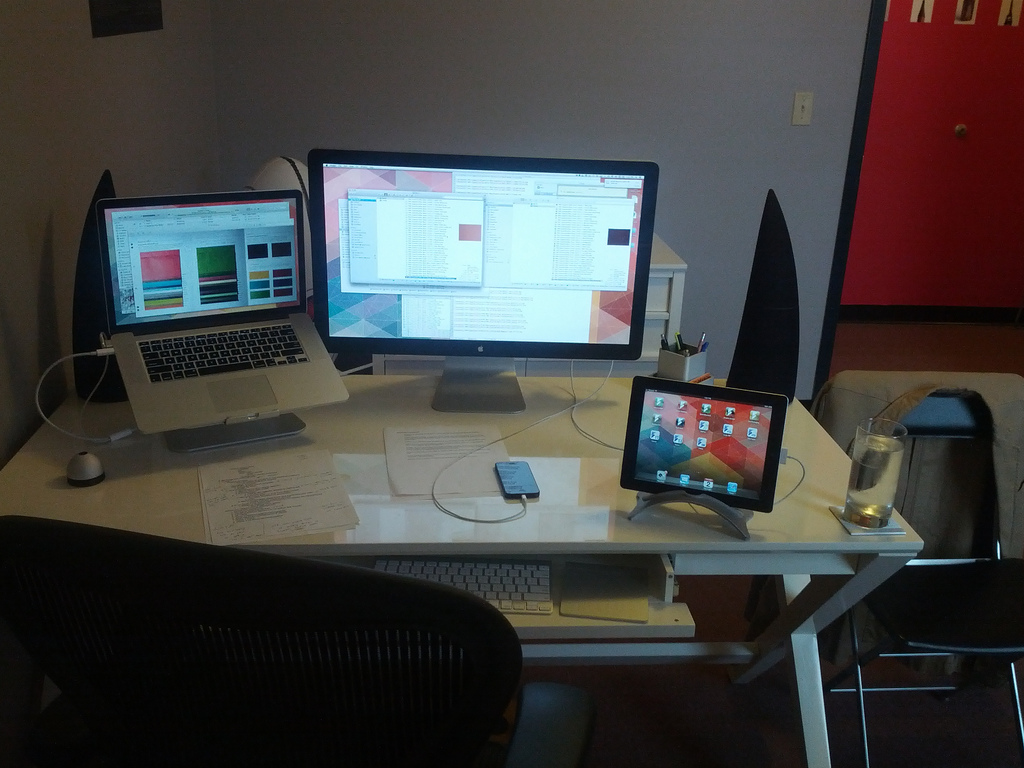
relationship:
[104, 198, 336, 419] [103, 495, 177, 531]
laptop on top of desk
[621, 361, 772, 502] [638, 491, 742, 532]
tablet on top of stand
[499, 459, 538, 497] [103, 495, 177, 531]
phone on top of desk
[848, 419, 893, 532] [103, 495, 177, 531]
glass on top of desk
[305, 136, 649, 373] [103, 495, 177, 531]
monitor on top of desk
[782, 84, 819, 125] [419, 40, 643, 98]
switch attached to wall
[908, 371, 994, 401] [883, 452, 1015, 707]
jacket on top of chair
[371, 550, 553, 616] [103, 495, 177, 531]
keyboard on top of desk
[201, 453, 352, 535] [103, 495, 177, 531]
papers on top of desk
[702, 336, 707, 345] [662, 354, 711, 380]
pens inside of container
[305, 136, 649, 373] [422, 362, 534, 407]
monitor of computer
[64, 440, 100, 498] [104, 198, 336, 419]
mouse next to laptop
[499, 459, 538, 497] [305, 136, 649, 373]
phone in front of monitor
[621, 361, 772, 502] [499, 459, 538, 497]
tablet next to phone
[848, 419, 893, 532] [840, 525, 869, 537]
glass on top of coaster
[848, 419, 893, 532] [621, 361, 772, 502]
glass next to tablet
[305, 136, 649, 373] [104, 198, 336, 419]
monitor next to laptop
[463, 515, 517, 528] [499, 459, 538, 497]
cable plugged into phone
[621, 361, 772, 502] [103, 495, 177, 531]
tablet on top of desk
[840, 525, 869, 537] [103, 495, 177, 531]
coaster on top of desk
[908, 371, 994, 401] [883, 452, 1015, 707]
jacket hanging from chair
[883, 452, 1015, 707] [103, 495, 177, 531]
chair in front of desk